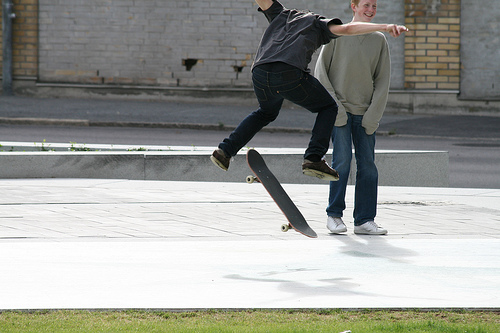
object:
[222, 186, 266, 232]
air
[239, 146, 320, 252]
skateboard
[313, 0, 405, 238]
other boy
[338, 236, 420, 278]
shadow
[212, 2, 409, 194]
skateboarder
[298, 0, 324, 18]
headless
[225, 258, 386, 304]
shadows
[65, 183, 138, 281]
ground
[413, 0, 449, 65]
wall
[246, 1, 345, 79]
shirt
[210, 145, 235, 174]
shoe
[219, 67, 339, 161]
jeans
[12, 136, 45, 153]
marking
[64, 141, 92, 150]
grass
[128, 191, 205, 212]
sidewalk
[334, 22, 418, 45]
arm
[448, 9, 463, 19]
brick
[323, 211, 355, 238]
shoes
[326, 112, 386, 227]
jeans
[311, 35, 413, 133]
sweater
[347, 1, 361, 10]
hair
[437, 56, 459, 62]
brick